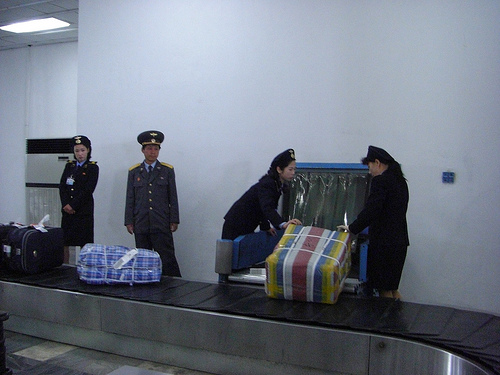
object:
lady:
[347, 145, 410, 307]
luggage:
[265, 216, 357, 304]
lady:
[211, 144, 305, 274]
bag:
[74, 243, 163, 285]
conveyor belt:
[3, 257, 493, 374]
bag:
[3, 221, 64, 280]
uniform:
[348, 171, 411, 294]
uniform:
[212, 174, 288, 239]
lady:
[54, 137, 98, 245]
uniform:
[58, 158, 100, 246]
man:
[121, 127, 188, 281]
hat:
[138, 130, 165, 148]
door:
[283, 168, 373, 280]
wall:
[76, 1, 499, 316]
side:
[2, 281, 483, 374]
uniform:
[123, 162, 188, 282]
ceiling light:
[1, 14, 72, 39]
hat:
[70, 135, 91, 146]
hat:
[271, 149, 298, 175]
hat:
[366, 145, 398, 167]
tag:
[113, 246, 140, 270]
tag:
[32, 222, 48, 232]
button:
[150, 184, 152, 186]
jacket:
[124, 157, 182, 232]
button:
[149, 191, 152, 193]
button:
[149, 199, 152, 201]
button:
[150, 207, 153, 209]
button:
[71, 188, 74, 190]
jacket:
[58, 157, 99, 214]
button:
[70, 196, 73, 198]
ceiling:
[0, 1, 83, 52]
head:
[144, 143, 160, 161]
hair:
[362, 156, 408, 182]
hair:
[266, 161, 292, 196]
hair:
[84, 144, 92, 160]